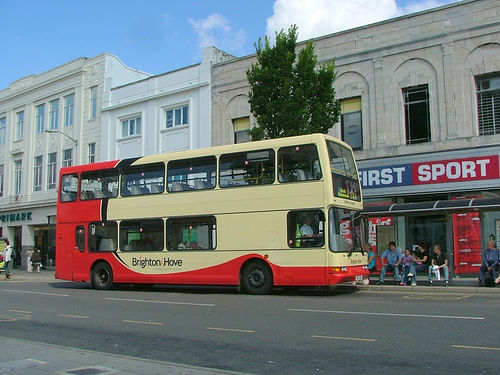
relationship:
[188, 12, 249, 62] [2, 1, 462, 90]
cloud in sky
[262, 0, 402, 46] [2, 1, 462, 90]
cloud in sky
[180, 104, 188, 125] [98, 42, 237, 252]
window adorning building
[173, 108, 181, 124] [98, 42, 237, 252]
window adorning building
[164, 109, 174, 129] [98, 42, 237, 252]
window adorning building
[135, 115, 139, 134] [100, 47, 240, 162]
window on a building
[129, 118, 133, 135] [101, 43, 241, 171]
window on a building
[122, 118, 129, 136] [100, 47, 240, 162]
window on a building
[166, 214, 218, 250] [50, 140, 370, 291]
window on a bus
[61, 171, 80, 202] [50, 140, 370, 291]
window on bus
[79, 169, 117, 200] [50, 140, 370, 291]
window on bus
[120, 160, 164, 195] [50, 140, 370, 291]
window on bus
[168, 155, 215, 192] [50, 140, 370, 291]
window on bus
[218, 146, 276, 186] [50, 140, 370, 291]
window on bus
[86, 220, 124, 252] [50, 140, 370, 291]
window on a bus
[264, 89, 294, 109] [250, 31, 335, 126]
leaf growing on plant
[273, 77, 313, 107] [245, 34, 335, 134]
leaf growing on plant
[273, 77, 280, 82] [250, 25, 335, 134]
leaf growing on plant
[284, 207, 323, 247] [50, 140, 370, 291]
window on bus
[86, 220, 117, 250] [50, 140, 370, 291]
window on bus